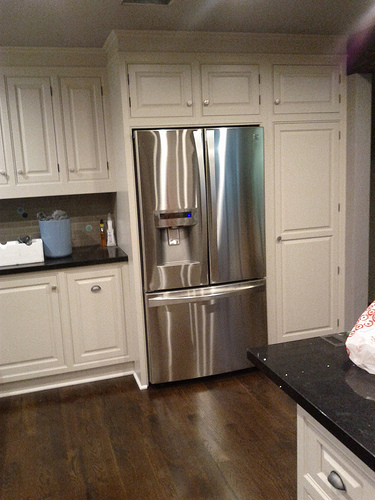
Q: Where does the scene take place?
A: In a kitchen.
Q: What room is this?
A: Kitchen.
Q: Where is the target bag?
A: Counter.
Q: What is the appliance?
A: Refrigerator.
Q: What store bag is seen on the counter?
A: Target.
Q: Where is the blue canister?
A: Counter next to fridge.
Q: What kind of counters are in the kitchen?
A: Black pearl granite.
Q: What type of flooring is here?
A: Wood.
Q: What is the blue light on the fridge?
A: Water and ice dispenser.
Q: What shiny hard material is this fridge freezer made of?
A: Stainless steel.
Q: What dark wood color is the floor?
A: Brown.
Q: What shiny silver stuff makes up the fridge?
A: Stainless steel.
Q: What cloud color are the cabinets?
A: White.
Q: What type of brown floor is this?
A: Wood.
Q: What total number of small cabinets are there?
A: Three.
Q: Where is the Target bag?
A: On the right counter.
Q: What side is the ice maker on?
A: Left.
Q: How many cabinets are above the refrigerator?
A: Two.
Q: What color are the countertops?
A: Black.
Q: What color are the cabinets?
A: White.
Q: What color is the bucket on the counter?
A: Blue.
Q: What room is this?
A: Kitchen.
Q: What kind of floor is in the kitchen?
A: Hardwood.